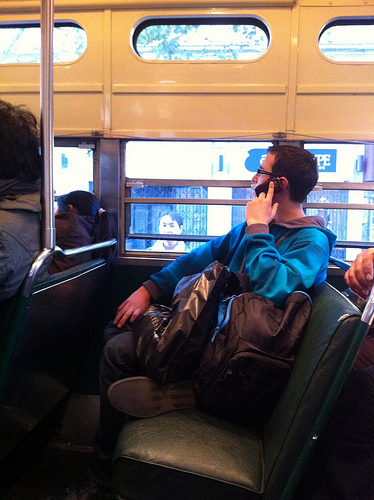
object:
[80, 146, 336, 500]
passenger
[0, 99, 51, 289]
man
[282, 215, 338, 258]
hood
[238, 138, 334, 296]
red building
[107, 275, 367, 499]
seat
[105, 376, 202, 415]
man's foot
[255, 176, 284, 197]
sky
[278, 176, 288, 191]
ear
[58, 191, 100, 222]
head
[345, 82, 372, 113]
ground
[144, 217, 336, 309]
blue sweater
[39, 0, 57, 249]
pole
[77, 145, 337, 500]
man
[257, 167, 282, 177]
glasses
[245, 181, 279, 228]
hand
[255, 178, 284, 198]
cell phone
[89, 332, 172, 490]
leg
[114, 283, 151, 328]
hand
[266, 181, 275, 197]
index finger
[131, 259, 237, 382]
bag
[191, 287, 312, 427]
backpack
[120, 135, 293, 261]
window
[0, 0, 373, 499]
bus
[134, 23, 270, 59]
window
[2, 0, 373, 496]
train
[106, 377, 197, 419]
sole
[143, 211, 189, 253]
man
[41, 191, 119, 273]
woman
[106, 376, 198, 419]
shoe